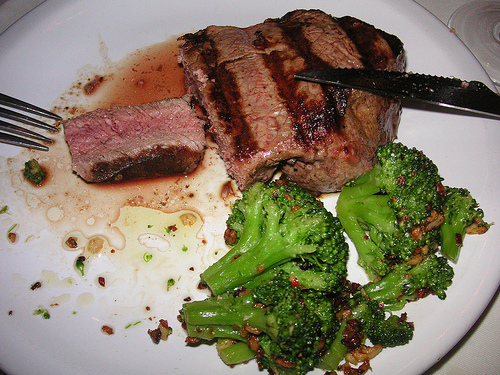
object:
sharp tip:
[294, 72, 303, 79]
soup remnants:
[110, 50, 185, 105]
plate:
[0, 0, 500, 372]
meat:
[62, 97, 206, 184]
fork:
[0, 93, 63, 151]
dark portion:
[95, 161, 186, 175]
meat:
[178, 8, 407, 193]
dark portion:
[212, 66, 235, 121]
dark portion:
[284, 28, 306, 113]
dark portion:
[354, 26, 375, 66]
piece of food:
[75, 256, 85, 276]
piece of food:
[98, 277, 105, 287]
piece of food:
[24, 159, 46, 185]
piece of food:
[65, 237, 78, 248]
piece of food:
[102, 325, 114, 335]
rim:
[395, 290, 500, 375]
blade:
[294, 67, 500, 121]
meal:
[0, 0, 499, 375]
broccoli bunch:
[179, 142, 494, 374]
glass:
[414, 1, 500, 94]